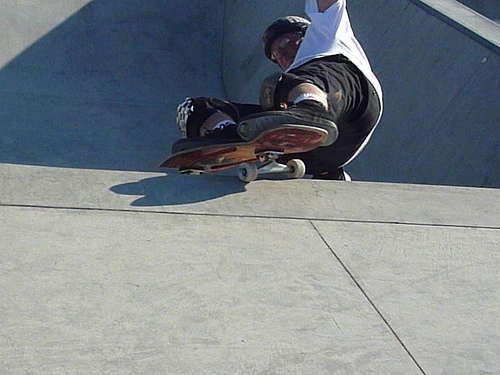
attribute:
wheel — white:
[291, 159, 307, 179]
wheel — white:
[236, 160, 259, 183]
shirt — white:
[285, 0, 384, 70]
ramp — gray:
[2, 160, 498, 372]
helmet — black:
[259, 15, 310, 51]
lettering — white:
[287, 14, 307, 22]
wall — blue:
[2, 1, 498, 185]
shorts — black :
[273, 54, 381, 173]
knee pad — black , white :
[176, 96, 211, 136]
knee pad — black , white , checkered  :
[176, 95, 201, 134]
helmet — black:
[261, 13, 311, 55]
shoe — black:
[169, 123, 240, 152]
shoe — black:
[234, 102, 339, 144]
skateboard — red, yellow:
[170, 115, 346, 184]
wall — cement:
[4, 4, 494, 367]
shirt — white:
[281, 6, 393, 106]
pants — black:
[320, 66, 346, 112]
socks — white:
[288, 87, 324, 109]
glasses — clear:
[252, 34, 316, 64]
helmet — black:
[249, 36, 279, 43]